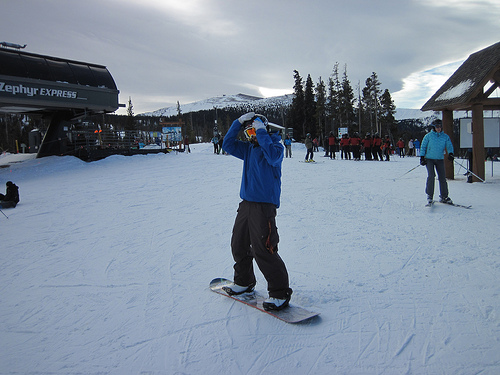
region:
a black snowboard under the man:
[203, 270, 325, 327]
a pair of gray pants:
[221, 196, 298, 305]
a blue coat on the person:
[216, 116, 293, 211]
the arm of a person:
[253, 128, 288, 168]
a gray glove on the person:
[249, 113, 273, 135]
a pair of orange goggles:
[242, 123, 259, 142]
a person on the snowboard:
[207, 100, 325, 335]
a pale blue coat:
[416, 129, 461, 166]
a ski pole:
[447, 154, 490, 194]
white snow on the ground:
[0, 134, 494, 371]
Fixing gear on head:
[222, 108, 287, 152]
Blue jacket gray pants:
[214, 106, 307, 298]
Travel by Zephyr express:
[2, 33, 132, 134]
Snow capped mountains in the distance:
[133, 68, 364, 124]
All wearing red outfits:
[316, 132, 407, 166]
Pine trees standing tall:
[277, 51, 416, 179]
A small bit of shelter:
[400, 31, 498, 218]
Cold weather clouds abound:
[154, 4, 464, 110]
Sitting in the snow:
[1, 173, 38, 223]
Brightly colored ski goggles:
[239, 117, 273, 145]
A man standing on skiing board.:
[200, 108, 324, 325]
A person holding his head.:
[225, 105, 291, 310]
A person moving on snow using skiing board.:
[402, 114, 488, 209]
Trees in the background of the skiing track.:
[141, 59, 421, 145]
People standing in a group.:
[285, 128, 418, 161]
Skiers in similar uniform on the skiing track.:
[315, 130, 394, 160]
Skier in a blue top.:
[224, 112, 292, 311]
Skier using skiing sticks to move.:
[401, 117, 479, 216]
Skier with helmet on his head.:
[423, 115, 448, 134]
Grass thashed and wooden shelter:
[420, 37, 497, 210]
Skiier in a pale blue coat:
[417, 117, 466, 221]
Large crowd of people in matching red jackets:
[326, 132, 396, 159]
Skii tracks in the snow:
[340, 211, 496, 372]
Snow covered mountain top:
[175, 91, 295, 107]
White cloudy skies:
[115, 6, 278, 91]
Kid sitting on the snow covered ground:
[1, 176, 22, 210]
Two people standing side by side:
[406, 134, 422, 158]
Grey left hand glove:
[250, 116, 267, 133]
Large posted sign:
[159, 123, 182, 150]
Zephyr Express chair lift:
[1, 40, 120, 115]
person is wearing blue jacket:
[216, 118, 283, 207]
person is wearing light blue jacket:
[416, 130, 454, 160]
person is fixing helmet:
[235, 111, 278, 131]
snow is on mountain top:
[149, 82, 296, 113]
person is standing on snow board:
[206, 107, 326, 329]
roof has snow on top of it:
[423, 45, 496, 105]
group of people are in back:
[321, 131, 406, 160]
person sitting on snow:
[1, 176, 21, 218]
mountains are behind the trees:
[134, 90, 289, 111]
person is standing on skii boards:
[391, 116, 485, 212]